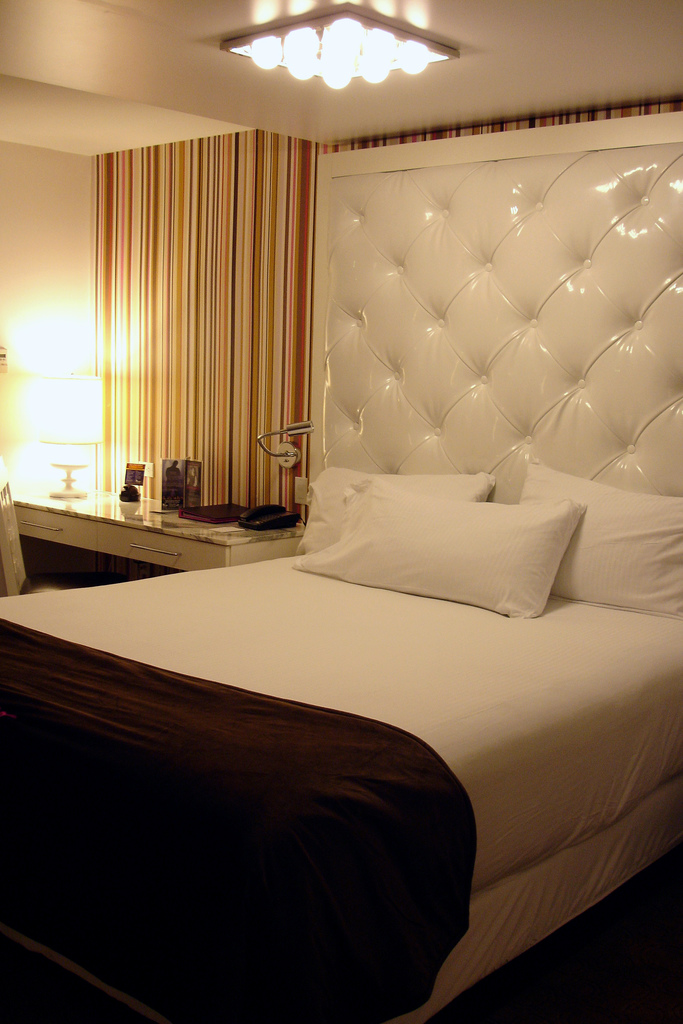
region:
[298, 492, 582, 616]
pillow on top of bed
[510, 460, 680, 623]
pillow on top of bed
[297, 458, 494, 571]
pillow on top of bed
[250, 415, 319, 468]
light attached to wall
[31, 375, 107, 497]
light on top of desk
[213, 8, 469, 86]
light on top of ceiling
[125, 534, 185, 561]
handle attached to drawer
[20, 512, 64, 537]
handle attached to drawer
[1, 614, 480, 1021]
blanket on top of bed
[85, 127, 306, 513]
The multi colored curtain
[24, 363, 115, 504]
The lamp that is turned on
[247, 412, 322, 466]
The silver desk lamp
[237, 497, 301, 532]
The black telephone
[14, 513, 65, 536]
The left drawer with the silver handle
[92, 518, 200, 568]
The right drawer with the silver handle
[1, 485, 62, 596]
The chair underneath the desk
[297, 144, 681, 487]
The white headboard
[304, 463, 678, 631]
The three white pillows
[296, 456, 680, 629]
The white pillows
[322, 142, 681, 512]
Quilted white leather headboard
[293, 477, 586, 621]
White pillow on bed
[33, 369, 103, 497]
Lamp with shade on desk beside bed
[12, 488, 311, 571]
White desk with silver drawer handles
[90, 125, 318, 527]
Multicolored striped wallpaper beside bed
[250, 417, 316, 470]
Adjustable wall-mounted reading lamp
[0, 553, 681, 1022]
Bed with white sheets and brown bedspread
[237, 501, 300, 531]
Modern black telephone on desk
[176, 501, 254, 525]
Dark red binder notebook on desk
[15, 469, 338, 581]
The desk has a marble counter top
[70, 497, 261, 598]
The drawer has a silver handle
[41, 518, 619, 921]
The sheets on the bed are white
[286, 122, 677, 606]
The head board is white pleather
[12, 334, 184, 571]
The white lamp is on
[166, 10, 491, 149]
The fixture on the ceiling is on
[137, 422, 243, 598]
There is a picture on the desk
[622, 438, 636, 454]
A button on a back board.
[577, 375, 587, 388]
A button on a back board.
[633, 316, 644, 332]
A button on a back board.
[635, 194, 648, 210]
A button on a back board.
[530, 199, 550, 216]
A button on a back board.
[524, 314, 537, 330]
A button on a back board.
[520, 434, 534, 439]
A button on a back board.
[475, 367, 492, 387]
A button on a back board.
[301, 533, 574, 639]
The white pillow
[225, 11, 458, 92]
Lightbulbs on the ceiling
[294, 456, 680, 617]
Three white pillows on the bed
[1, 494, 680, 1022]
White sheets on the bed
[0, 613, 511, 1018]
Brown comforter on the bed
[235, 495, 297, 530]
Black phone on the table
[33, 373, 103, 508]
Lamp on the table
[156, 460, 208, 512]
Picture frame on table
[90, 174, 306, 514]
Colorful striped wallpaper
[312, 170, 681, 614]
Big white bed frame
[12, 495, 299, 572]
Table next to the bed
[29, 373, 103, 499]
white table lamp with a white shade